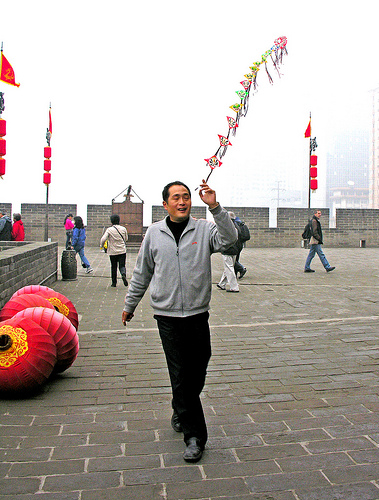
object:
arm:
[203, 206, 238, 252]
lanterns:
[42, 145, 52, 185]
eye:
[183, 195, 188, 201]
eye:
[174, 195, 179, 201]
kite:
[197, 35, 288, 194]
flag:
[304, 120, 313, 141]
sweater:
[123, 202, 239, 319]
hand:
[197, 178, 217, 205]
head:
[161, 179, 193, 217]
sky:
[1, 1, 379, 226]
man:
[302, 212, 337, 274]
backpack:
[301, 218, 314, 242]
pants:
[151, 314, 214, 439]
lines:
[27, 406, 197, 493]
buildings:
[303, 90, 378, 212]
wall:
[251, 208, 379, 247]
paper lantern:
[6, 281, 65, 297]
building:
[0, 197, 379, 257]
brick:
[277, 216, 285, 223]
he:
[112, 179, 239, 462]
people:
[0, 208, 13, 241]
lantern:
[1, 307, 76, 404]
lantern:
[3, 284, 78, 334]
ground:
[0, 245, 378, 497]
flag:
[1, 53, 22, 89]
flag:
[48, 107, 54, 135]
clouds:
[2, 0, 379, 208]